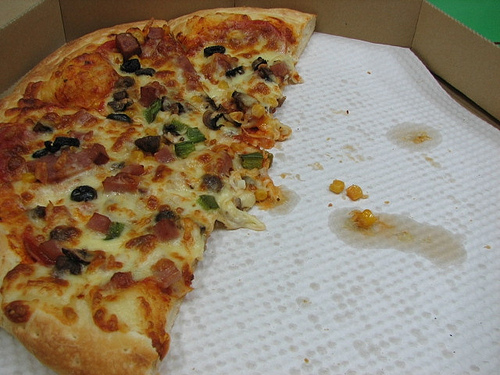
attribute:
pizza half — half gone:
[6, 5, 316, 374]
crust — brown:
[26, 322, 156, 372]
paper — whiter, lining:
[158, 29, 498, 374]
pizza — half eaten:
[0, 0, 316, 374]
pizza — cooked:
[10, 38, 219, 355]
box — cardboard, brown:
[1, 0, 498, 372]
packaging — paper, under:
[3, 32, 497, 372]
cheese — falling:
[207, 199, 268, 234]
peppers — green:
[154, 108, 275, 217]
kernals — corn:
[98, 49, 221, 158]